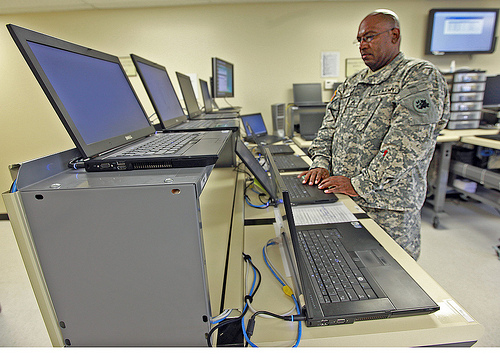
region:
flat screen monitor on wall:
[423, 5, 498, 65]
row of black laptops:
[10, 22, 240, 190]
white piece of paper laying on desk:
[282, 192, 354, 229]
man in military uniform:
[312, 0, 456, 262]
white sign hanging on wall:
[312, 49, 343, 78]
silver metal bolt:
[39, 177, 66, 195]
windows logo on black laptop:
[347, 217, 367, 232]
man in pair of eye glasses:
[340, 4, 411, 74]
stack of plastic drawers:
[444, 59, 489, 134]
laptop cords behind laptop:
[235, 234, 297, 340]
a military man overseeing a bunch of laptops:
[5, 9, 455, 332]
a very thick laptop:
[268, 193, 428, 334]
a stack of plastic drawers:
[442, 63, 495, 146]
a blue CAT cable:
[255, 245, 306, 304]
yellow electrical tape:
[281, 285, 290, 302]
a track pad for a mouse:
[352, 245, 401, 275]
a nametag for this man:
[362, 85, 404, 102]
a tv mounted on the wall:
[430, 10, 497, 66]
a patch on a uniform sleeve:
[403, 85, 446, 132]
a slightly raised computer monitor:
[205, 44, 259, 106]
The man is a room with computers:
[25, 13, 495, 335]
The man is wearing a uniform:
[20, 6, 480, 336]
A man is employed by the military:
[1, 16, 481, 326]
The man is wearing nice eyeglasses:
[320, 5, 421, 85]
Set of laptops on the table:
[5, 19, 443, 323]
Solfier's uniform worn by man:
[307, 48, 447, 264]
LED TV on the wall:
[422, 7, 499, 57]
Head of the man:
[355, 10, 407, 72]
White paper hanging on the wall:
[320, 51, 342, 76]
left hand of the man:
[315, 174, 360, 197]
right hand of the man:
[293, 165, 331, 186]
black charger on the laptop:
[215, 249, 307, 347]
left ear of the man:
[389, 27, 400, 45]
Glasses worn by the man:
[351, 27, 398, 46]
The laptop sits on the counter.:
[278, 190, 442, 324]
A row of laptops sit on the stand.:
[8, 24, 240, 163]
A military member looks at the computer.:
[307, 4, 439, 260]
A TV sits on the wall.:
[423, 3, 498, 46]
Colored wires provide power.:
[209, 230, 304, 346]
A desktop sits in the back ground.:
[208, 52, 248, 112]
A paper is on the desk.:
[287, 200, 356, 222]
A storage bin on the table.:
[448, 65, 488, 129]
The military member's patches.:
[396, 82, 441, 127]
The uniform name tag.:
[368, 87, 402, 95]